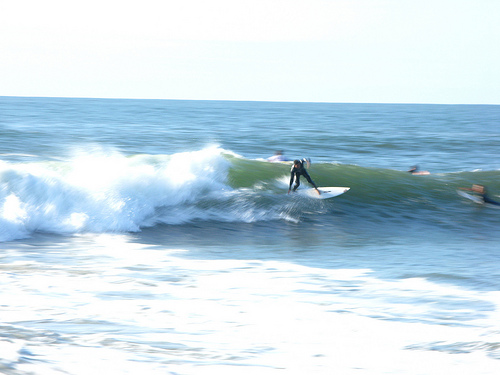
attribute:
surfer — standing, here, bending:
[276, 156, 315, 192]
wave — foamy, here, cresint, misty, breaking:
[25, 129, 481, 242]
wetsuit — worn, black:
[284, 167, 324, 189]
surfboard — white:
[280, 188, 366, 206]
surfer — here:
[451, 167, 490, 224]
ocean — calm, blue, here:
[52, 86, 462, 160]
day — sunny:
[5, 44, 382, 111]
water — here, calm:
[81, 248, 401, 296]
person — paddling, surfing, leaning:
[283, 150, 323, 196]